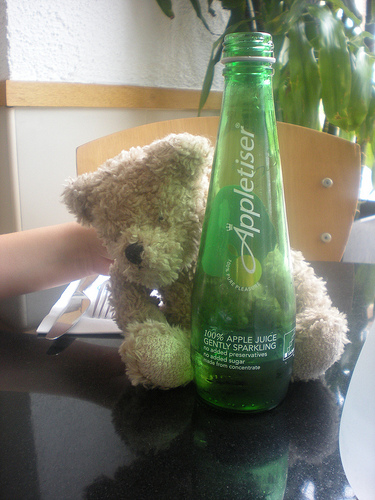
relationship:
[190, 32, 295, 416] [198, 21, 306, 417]
bottle has apple juice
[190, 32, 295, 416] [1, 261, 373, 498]
bottle on table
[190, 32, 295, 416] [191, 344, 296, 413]
bottle contains apple juice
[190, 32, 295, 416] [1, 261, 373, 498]
bottle sitting on table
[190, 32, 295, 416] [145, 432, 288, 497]
bottle sitting on table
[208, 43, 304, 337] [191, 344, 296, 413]
bottle contains apple juice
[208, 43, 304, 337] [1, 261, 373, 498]
bottle sitting on table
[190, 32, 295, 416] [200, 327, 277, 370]
bottle contains apple juice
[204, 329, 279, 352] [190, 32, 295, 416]
words painted on bottle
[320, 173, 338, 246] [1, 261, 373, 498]
rivets on table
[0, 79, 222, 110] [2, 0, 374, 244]
strip on wall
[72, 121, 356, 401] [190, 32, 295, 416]
bear behind bottle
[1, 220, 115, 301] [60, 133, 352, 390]
person's arm holding bear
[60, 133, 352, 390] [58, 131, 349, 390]
bear behind bear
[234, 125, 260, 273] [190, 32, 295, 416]
word on bottle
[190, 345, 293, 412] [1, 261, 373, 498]
apple juice on table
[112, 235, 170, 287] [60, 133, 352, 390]
mouth on bear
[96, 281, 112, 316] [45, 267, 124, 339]
fork on napkin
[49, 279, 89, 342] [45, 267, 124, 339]
knife on napkin